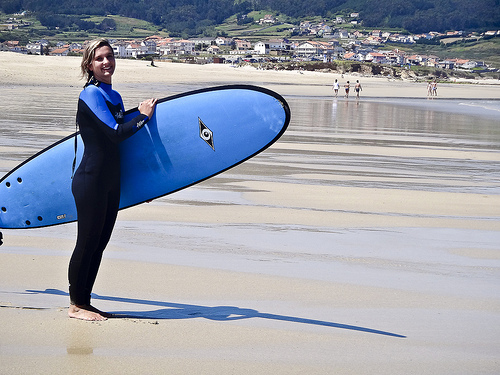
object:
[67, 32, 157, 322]
lady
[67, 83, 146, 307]
wet suit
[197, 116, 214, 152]
logo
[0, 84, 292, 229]
board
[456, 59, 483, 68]
buildings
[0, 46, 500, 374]
beach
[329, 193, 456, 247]
sand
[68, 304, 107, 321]
feet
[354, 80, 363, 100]
people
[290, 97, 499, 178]
water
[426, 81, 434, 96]
people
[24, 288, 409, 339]
shadow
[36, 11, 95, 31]
tree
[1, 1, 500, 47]
horizon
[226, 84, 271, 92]
black border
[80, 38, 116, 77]
head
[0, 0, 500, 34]
mountains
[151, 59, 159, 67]
person